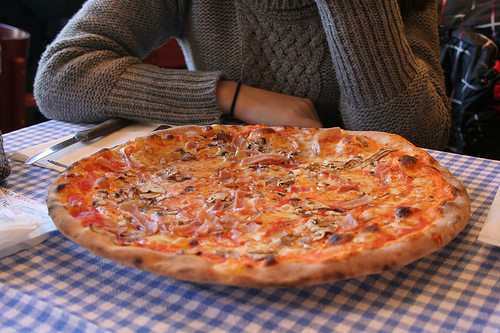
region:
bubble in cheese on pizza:
[252, 126, 281, 137]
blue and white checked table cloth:
[80, 288, 157, 322]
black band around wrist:
[228, 75, 243, 115]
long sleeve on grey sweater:
[115, 66, 232, 123]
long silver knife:
[17, 133, 102, 167]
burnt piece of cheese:
[394, 206, 416, 219]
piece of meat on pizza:
[97, 157, 129, 175]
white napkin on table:
[66, 149, 78, 160]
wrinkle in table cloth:
[11, 287, 71, 317]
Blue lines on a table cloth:
[7, 295, 51, 332]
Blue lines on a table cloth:
[5, 253, 47, 299]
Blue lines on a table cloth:
[29, 283, 83, 331]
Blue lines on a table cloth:
[44, 239, 83, 290]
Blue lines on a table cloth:
[61, 288, 106, 330]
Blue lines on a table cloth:
[94, 289, 149, 326]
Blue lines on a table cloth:
[195, 293, 235, 330]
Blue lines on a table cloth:
[222, 294, 265, 330]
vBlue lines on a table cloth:
[285, 295, 313, 323]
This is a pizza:
[38, 123, 471, 276]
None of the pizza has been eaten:
[61, 118, 466, 288]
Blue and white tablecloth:
[10, 260, 484, 329]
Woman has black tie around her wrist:
[220, 68, 249, 117]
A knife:
[15, 120, 129, 167]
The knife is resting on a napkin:
[15, 118, 132, 173]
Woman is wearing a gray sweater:
[35, 5, 442, 112]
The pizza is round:
[51, 125, 458, 282]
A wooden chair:
[1, 14, 36, 118]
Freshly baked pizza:
[43, 119, 473, 291]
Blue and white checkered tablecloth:
[1, 117, 499, 332]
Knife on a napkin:
[21, 115, 123, 170]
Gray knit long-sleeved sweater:
[29, 0, 459, 155]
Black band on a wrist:
[221, 77, 248, 116]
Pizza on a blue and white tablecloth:
[43, 119, 476, 292]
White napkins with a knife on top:
[10, 118, 167, 175]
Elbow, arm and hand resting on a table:
[27, 43, 323, 134]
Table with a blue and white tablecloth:
[0, 116, 499, 331]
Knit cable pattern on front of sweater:
[230, 18, 328, 100]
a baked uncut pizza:
[43, 122, 472, 290]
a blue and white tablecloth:
[1, 121, 498, 331]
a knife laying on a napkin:
[11, 123, 179, 172]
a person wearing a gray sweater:
[33, 1, 448, 146]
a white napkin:
[479, 180, 499, 254]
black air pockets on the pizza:
[323, 205, 420, 245]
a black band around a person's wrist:
[223, 81, 242, 118]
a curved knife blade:
[20, 115, 126, 162]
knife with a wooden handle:
[24, 116, 124, 163]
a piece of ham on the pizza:
[238, 153, 288, 168]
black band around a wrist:
[228, 80, 242, 115]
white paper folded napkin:
[11, 120, 176, 168]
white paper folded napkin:
[476, 182, 498, 247]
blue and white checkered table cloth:
[3, 118, 498, 331]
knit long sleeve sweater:
[31, 5, 450, 146]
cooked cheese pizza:
[45, 121, 471, 284]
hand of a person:
[218, 78, 321, 125]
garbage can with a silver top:
[1, 25, 30, 135]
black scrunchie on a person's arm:
[228, 81, 240, 117]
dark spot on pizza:
[56, 180, 69, 192]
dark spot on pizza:
[64, 170, 78, 181]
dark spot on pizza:
[63, 164, 76, 171]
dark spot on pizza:
[131, 253, 143, 266]